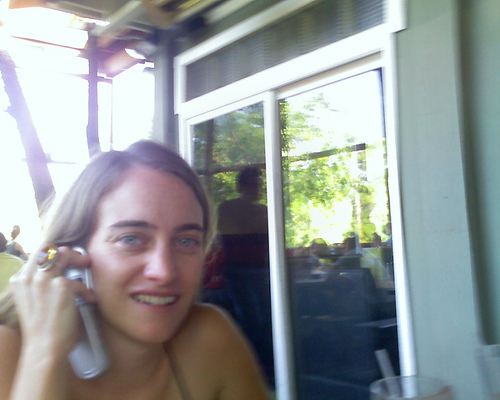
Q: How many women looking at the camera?
A: 1.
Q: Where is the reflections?
A: Glass doors.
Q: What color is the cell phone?
A: Silver.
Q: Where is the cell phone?
A: Woman's right hand.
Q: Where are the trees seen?
A: Reflection.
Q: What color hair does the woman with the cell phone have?
A: Blonde.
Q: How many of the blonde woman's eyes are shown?
A: 2.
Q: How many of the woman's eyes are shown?
A: 2.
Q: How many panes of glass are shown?
A: 2.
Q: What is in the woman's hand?
A: Phone.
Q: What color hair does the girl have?
A: Blonde.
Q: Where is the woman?
A: On a porch.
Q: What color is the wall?
A: Grey.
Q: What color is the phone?
A: Silver.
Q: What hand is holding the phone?
A: Right.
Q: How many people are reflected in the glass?
A: One.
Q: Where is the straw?
A: In the glass.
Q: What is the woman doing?
A: Talking on the phone.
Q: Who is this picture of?
A: A girl.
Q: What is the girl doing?
A: Talking on the phone.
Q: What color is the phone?
A: Silver.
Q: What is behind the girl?
A: A window.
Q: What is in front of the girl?
A: A cup.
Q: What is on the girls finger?
A: A ring.